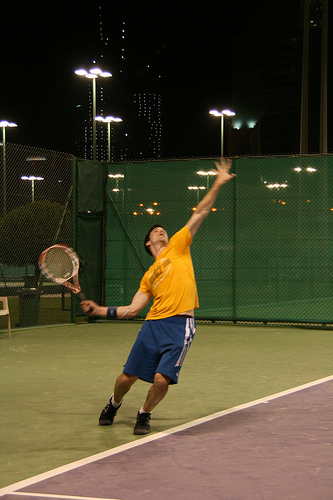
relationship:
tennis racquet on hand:
[29, 241, 103, 327] [201, 152, 240, 189]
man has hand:
[80, 156, 236, 433] [201, 152, 240, 189]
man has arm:
[80, 156, 236, 433] [178, 143, 244, 240]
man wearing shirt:
[80, 156, 236, 433] [137, 221, 203, 319]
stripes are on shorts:
[165, 314, 204, 384] [119, 300, 206, 396]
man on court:
[80, 156, 236, 433] [5, 310, 331, 498]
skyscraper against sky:
[74, 3, 162, 161] [1, 0, 332, 157]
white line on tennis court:
[17, 363, 317, 492] [4, 320, 322, 498]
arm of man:
[181, 160, 235, 253] [80, 156, 236, 435]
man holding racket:
[80, 156, 236, 435] [34, 240, 100, 324]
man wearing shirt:
[80, 156, 236, 433] [140, 225, 203, 322]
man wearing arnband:
[80, 156, 236, 435] [101, 298, 122, 321]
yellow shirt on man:
[137, 223, 199, 321] [80, 156, 236, 433]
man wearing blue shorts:
[80, 156, 236, 435] [130, 321, 191, 382]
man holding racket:
[80, 156, 236, 435] [38, 243, 93, 317]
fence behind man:
[246, 156, 324, 329] [37, 172, 277, 465]